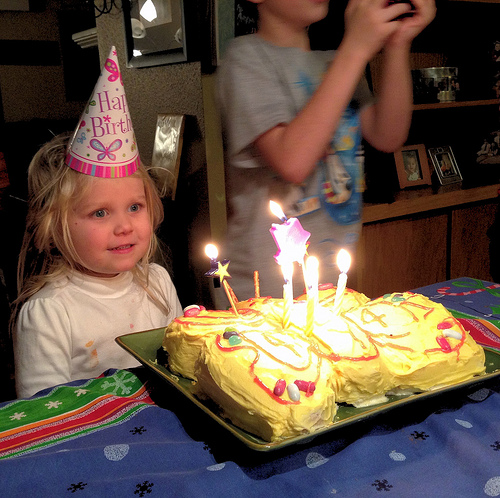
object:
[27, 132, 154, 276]
head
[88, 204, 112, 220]
eye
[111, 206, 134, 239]
nose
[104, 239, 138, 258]
mouth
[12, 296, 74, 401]
arm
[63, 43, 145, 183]
hat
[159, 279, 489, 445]
cake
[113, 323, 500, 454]
platter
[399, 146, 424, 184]
picture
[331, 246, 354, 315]
candle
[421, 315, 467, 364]
icing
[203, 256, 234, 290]
star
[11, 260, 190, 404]
shirt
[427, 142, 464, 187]
frame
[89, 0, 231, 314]
wall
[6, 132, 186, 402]
child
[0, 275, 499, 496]
cloth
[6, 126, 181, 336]
hair